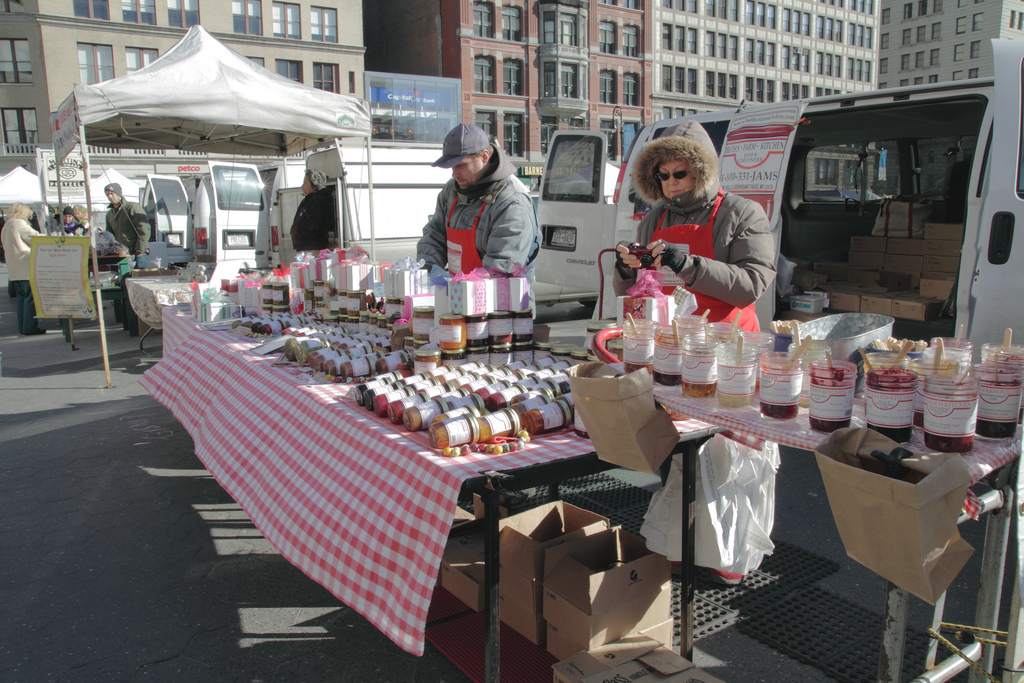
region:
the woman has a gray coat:
[603, 96, 787, 353]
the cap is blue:
[419, 109, 508, 170]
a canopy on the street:
[30, 6, 403, 396]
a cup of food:
[913, 349, 993, 466]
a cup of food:
[865, 344, 927, 447]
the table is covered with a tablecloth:
[117, 267, 615, 667]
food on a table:
[192, 232, 603, 492]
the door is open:
[182, 140, 296, 287]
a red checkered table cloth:
[146, 297, 619, 651]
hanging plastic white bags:
[647, 443, 787, 570]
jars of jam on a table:
[362, 349, 588, 458]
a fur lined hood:
[624, 115, 732, 198]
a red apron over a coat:
[634, 193, 772, 343]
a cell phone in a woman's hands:
[621, 237, 682, 273]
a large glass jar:
[813, 351, 858, 434]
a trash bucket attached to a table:
[820, 424, 976, 601]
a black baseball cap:
[431, 123, 489, 166]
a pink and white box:
[437, 266, 530, 320]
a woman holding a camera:
[584, 119, 782, 354]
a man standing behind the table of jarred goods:
[394, 117, 551, 343]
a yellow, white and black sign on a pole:
[18, 231, 114, 334]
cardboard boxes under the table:
[502, 500, 686, 665]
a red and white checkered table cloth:
[136, 287, 640, 638]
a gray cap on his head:
[413, 126, 487, 172]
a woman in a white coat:
[6, 196, 46, 336]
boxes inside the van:
[806, 198, 962, 332]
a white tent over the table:
[38, 25, 383, 329]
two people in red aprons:
[422, 111, 803, 375]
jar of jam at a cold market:
[610, 302, 656, 369]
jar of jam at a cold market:
[650, 318, 689, 386]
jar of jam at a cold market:
[683, 333, 716, 394]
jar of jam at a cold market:
[718, 340, 748, 411]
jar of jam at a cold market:
[751, 340, 796, 417]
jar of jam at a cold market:
[801, 359, 852, 424]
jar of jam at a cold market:
[864, 359, 909, 446]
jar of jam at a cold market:
[918, 362, 982, 440]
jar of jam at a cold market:
[974, 349, 1019, 433]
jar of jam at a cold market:
[434, 407, 480, 452]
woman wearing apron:
[640, 209, 761, 318]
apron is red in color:
[643, 187, 752, 314]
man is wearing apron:
[438, 203, 502, 293]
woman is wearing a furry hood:
[627, 109, 730, 202]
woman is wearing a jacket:
[622, 133, 781, 315]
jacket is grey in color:
[611, 101, 777, 302]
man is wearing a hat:
[442, 118, 531, 188]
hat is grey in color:
[431, 118, 502, 164]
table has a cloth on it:
[175, 253, 627, 615]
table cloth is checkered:
[241, 405, 444, 602]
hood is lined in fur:
[626, 113, 730, 205]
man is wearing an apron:
[438, 176, 507, 269]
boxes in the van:
[813, 191, 962, 338]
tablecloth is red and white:
[150, 322, 506, 668]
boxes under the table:
[494, 482, 695, 677]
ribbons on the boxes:
[447, 249, 534, 316]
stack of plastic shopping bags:
[642, 435, 781, 573]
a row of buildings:
[3, 7, 939, 140]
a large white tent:
[43, 45, 389, 358]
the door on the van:
[790, 133, 965, 310]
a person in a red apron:
[637, 124, 742, 302]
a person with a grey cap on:
[427, 116, 519, 279]